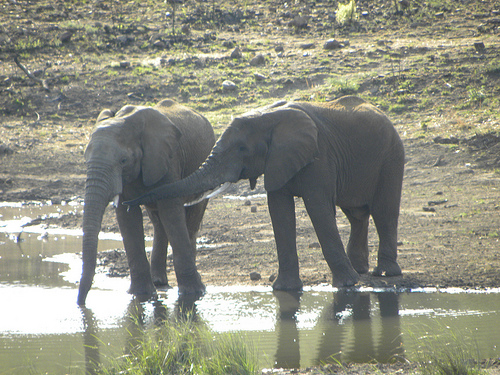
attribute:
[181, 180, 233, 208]
tusk — white 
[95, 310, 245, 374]
grass — green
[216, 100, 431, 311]
elephants — gray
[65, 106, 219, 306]
jumbo — short 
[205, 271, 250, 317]
light — white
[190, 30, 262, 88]
grass — rock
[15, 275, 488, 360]
area — marshy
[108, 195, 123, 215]
tusk — ivory, very short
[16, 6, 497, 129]
hill — sloping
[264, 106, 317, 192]
ear — large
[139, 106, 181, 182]
ear — large